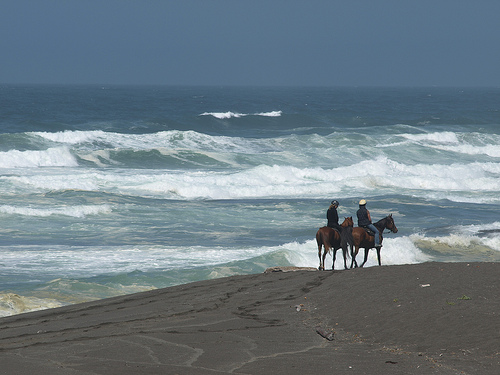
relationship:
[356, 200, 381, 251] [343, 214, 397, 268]
person riding horse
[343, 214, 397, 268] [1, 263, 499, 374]
horse on top of beach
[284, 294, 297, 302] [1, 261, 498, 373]
hoof print on top of sand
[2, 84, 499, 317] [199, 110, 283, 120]
ocean has wave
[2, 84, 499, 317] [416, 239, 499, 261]
ocean has foam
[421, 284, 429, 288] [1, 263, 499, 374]
stick on top of beach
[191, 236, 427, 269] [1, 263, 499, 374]
wave breaking on beach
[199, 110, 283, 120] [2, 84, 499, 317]
wave on top of ocean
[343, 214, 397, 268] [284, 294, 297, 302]
horse leving hoof print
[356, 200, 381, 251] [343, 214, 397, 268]
person on top of horse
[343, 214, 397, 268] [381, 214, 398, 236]
horse has head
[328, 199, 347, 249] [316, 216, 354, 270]
rider sitting on horse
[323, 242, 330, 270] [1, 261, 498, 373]
horse's leg walking on sand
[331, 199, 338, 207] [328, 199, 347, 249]
helmet on top of rider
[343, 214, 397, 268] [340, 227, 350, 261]
horse has tail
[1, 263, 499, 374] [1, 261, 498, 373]
beach has sand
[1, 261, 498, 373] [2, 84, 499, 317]
sand next to ocean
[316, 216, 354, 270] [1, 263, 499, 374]
horse on top of beach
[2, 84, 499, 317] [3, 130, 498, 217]
ocean has wave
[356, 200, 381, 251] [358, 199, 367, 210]
person has helmet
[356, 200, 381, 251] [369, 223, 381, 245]
person wearing jeans